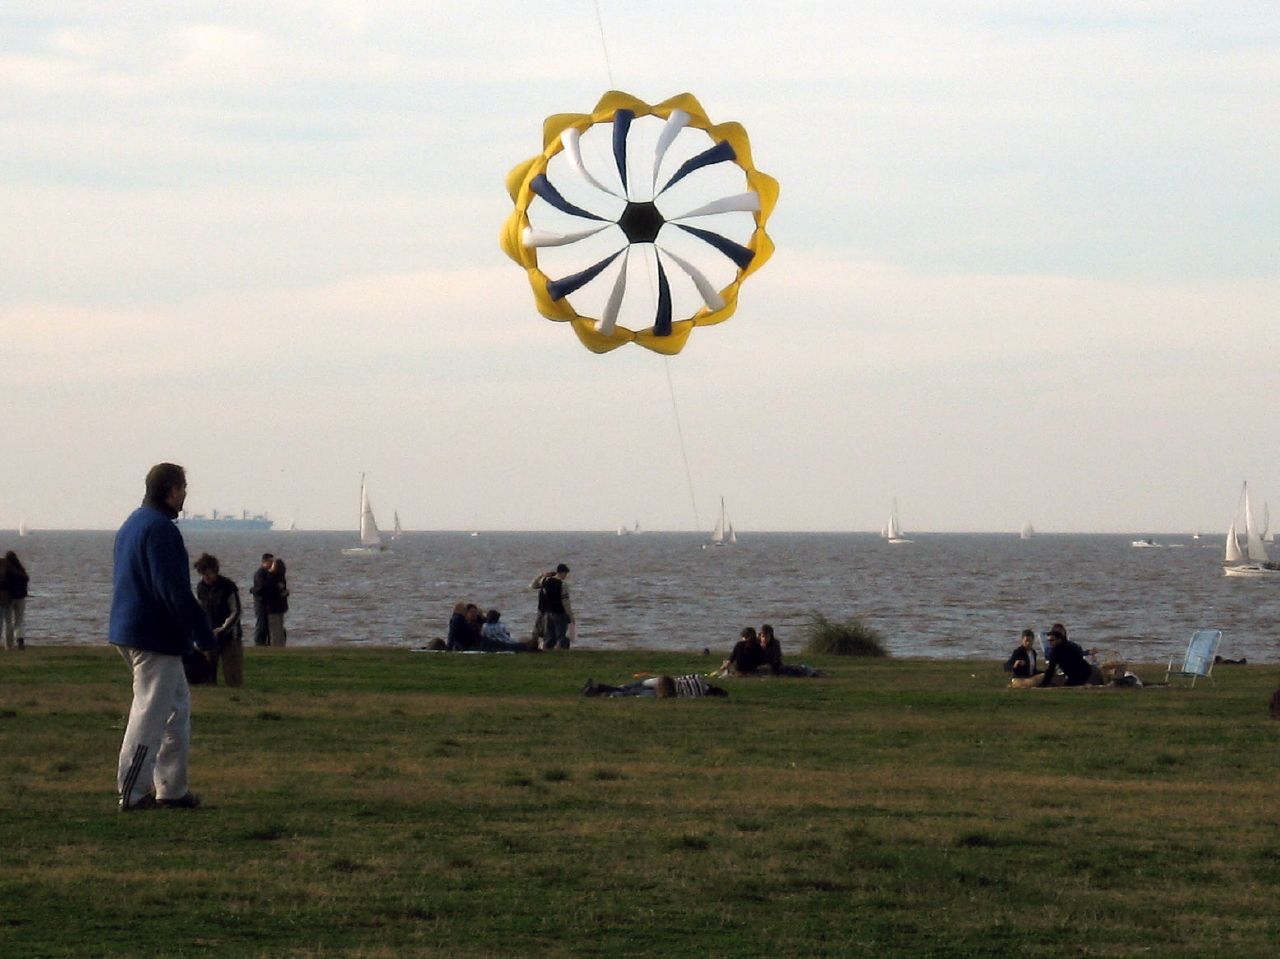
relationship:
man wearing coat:
[82, 453, 219, 804] [112, 502, 209, 655]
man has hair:
[82, 453, 219, 804] [147, 458, 188, 499]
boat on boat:
[1219, 481, 1280, 583] [350, 486, 375, 532]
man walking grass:
[100, 462, 222, 811] [31, 637, 1227, 902]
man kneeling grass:
[100, 462, 222, 811] [17, 653, 1231, 918]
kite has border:
[494, 88, 801, 357] [494, 83, 796, 352]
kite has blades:
[494, 89, 801, 358] [571, 132, 710, 301]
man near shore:
[100, 462, 222, 811] [279, 615, 1242, 687]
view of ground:
[463, 732, 840, 941] [588, 750, 1067, 938]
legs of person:
[79, 655, 281, 850] [53, 434, 295, 848]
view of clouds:
[882, 92, 1082, 429] [868, 208, 1112, 401]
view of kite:
[416, 61, 1037, 531] [494, 89, 801, 358]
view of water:
[568, 527, 719, 617] [630, 557, 832, 680]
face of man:
[125, 445, 229, 596] [100, 462, 222, 811]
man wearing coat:
[100, 462, 222, 811] [108, 507, 201, 665]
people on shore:
[436, 558, 589, 653] [38, 619, 1234, 744]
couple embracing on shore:
[254, 542, 295, 656] [10, 630, 1238, 685]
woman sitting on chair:
[1048, 623, 1075, 683] [1027, 656, 1131, 688]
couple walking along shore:
[540, 565, 579, 653] [31, 621, 1222, 714]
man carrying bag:
[100, 462, 222, 811] [187, 591, 235, 663]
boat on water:
[333, 470, 384, 574] [7, 518, 1238, 657]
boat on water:
[1218, 493, 1241, 553] [7, 518, 1238, 657]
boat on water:
[878, 495, 915, 562] [7, 518, 1238, 657]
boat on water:
[696, 486, 735, 551] [7, 518, 1238, 657]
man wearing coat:
[100, 462, 222, 811] [108, 505, 212, 660]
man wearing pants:
[100, 462, 222, 811] [122, 644, 191, 799]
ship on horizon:
[173, 505, 289, 539] [3, 516, 1206, 597]